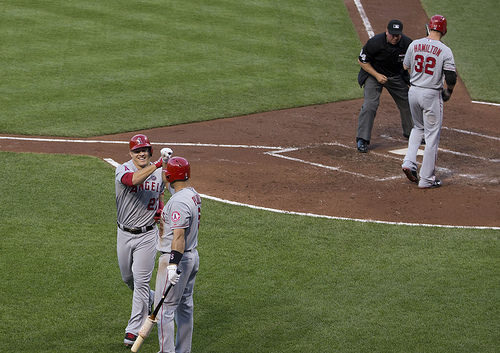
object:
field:
[4, 3, 495, 349]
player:
[114, 132, 166, 342]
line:
[205, 140, 296, 154]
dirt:
[208, 159, 318, 202]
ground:
[0, 0, 497, 348]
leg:
[420, 91, 444, 187]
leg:
[403, 88, 422, 187]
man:
[400, 11, 460, 189]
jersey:
[153, 185, 205, 256]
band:
[167, 249, 182, 267]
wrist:
[163, 243, 189, 273]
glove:
[167, 264, 180, 283]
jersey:
[113, 159, 163, 228]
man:
[112, 132, 162, 346]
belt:
[111, 220, 158, 237]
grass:
[0, 151, 499, 352]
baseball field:
[2, 0, 499, 352]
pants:
[157, 249, 200, 351]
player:
[154, 156, 204, 351]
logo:
[139, 177, 168, 195]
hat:
[384, 27, 407, 38]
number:
[410, 50, 439, 82]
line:
[293, 201, 418, 228]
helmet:
[124, 134, 152, 156]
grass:
[0, 0, 376, 136]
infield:
[0, 0, 369, 140]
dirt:
[273, 172, 309, 201]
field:
[206, 143, 382, 308]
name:
[408, 34, 448, 63]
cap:
[386, 17, 409, 38]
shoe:
[341, 132, 368, 159]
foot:
[346, 139, 376, 161]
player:
[388, 6, 460, 200]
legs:
[395, 106, 449, 191]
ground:
[182, 75, 351, 171]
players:
[104, 121, 209, 351]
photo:
[6, 3, 498, 348]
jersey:
[401, 35, 459, 93]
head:
[375, 12, 413, 53]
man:
[346, 12, 407, 157]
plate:
[386, 137, 426, 160]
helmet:
[127, 129, 153, 156]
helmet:
[162, 155, 192, 180]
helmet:
[428, 11, 447, 32]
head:
[127, 134, 154, 168]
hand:
[163, 260, 186, 286]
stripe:
[157, 300, 165, 349]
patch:
[168, 205, 183, 223]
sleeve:
[160, 197, 190, 231]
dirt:
[0, 6, 500, 226]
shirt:
[399, 33, 460, 93]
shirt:
[157, 182, 202, 256]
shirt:
[113, 161, 165, 223]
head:
[163, 153, 193, 185]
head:
[425, 11, 450, 41]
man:
[149, 156, 208, 352]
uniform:
[113, 156, 164, 336]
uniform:
[154, 182, 202, 351]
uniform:
[357, 30, 414, 140]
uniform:
[401, 38, 455, 187]